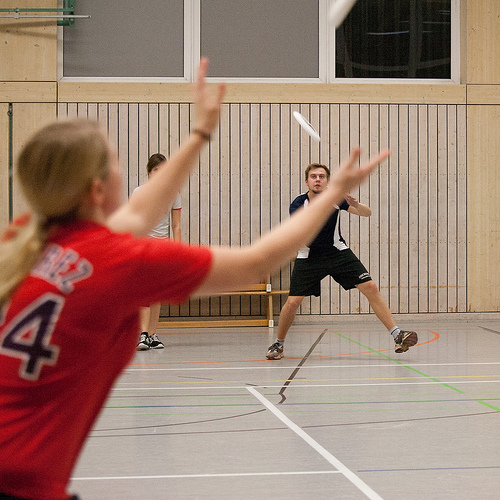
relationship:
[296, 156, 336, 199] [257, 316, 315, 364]
man has foot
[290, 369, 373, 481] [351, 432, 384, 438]
part of floor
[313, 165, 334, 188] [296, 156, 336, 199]
face of man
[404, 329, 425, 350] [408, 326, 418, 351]
sole of shoe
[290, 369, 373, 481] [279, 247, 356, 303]
part of short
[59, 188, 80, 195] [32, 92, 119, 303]
hair of lady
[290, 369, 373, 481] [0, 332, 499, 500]
part of floor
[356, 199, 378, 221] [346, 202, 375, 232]
part of bicep